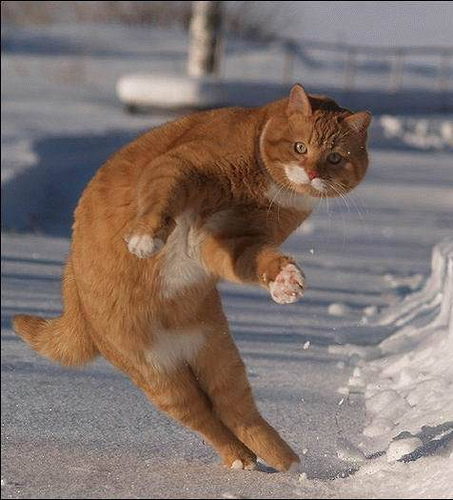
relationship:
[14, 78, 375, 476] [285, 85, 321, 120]
cat has ear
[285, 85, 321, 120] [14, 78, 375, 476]
ear of cat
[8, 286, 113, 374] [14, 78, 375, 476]
tail of cat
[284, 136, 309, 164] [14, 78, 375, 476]
eye of cat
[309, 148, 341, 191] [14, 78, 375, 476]
nose of cat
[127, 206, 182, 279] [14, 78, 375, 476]
paw of cat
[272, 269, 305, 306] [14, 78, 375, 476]
claw of cat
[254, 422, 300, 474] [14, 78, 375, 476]
feet of cat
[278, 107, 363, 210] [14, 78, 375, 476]
facial expression on cat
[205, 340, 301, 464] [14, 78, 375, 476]
leg of cat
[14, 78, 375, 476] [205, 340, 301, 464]
cat has leg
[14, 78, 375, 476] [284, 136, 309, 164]
cat has eye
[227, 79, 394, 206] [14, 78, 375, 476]
head of cat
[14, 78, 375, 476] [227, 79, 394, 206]
cat has head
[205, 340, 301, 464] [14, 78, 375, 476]
leg on cat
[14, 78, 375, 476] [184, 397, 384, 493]
cat has feet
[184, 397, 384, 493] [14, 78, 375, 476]
feet of cat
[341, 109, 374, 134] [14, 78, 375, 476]
ear of cat